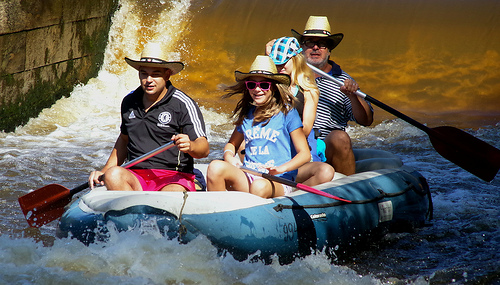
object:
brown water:
[14, 0, 500, 130]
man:
[291, 15, 374, 176]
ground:
[361, 154, 405, 205]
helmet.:
[268, 36, 304, 66]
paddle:
[17, 140, 177, 229]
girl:
[263, 35, 335, 193]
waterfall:
[101, 0, 500, 132]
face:
[250, 81, 271, 104]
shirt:
[234, 102, 304, 182]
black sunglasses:
[301, 40, 329, 50]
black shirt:
[119, 80, 208, 175]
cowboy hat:
[123, 42, 184, 76]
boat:
[55, 148, 435, 266]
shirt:
[312, 60, 374, 140]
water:
[352, 47, 474, 84]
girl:
[206, 55, 311, 199]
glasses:
[245, 81, 273, 91]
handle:
[69, 140, 177, 196]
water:
[1, 211, 361, 280]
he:
[86, 42, 209, 192]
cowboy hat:
[290, 16, 343, 51]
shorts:
[127, 169, 196, 192]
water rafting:
[16, 13, 500, 263]